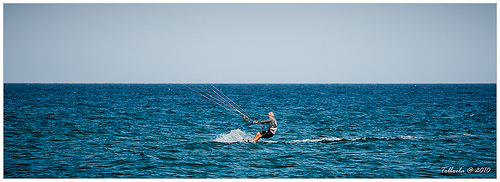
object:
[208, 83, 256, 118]
strings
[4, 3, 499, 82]
blue sky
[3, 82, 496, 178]
ocean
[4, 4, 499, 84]
clouds